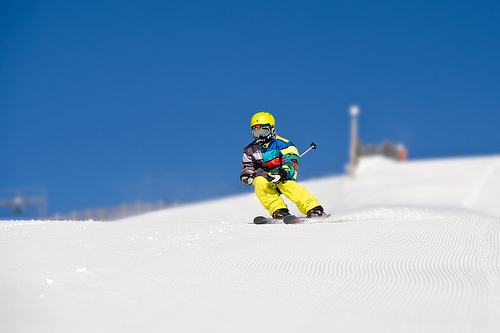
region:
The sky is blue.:
[30, 34, 150, 123]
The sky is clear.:
[34, 29, 195, 145]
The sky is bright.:
[35, 28, 204, 165]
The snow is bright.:
[108, 249, 313, 331]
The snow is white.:
[148, 244, 398, 325]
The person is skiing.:
[229, 104, 351, 231]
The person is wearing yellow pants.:
[213, 97, 340, 227]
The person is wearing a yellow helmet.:
[236, 95, 289, 142]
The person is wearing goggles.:
[237, 106, 283, 147]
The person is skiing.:
[223, 100, 343, 233]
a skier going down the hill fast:
[235, 102, 340, 232]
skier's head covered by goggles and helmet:
[244, 105, 281, 147]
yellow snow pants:
[245, 167, 339, 226]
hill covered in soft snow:
[6, 144, 498, 324]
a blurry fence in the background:
[26, 190, 202, 228]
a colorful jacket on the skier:
[233, 135, 303, 190]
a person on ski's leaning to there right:
[240, 103, 352, 236]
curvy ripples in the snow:
[226, 237, 492, 292]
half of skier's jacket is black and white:
[234, 138, 273, 192]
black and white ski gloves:
[234, 167, 306, 192]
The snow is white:
[231, 244, 302, 288]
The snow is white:
[250, 280, 337, 331]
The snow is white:
[272, 271, 319, 329]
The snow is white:
[290, 274, 325, 306]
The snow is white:
[290, 247, 340, 302]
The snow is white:
[268, 250, 336, 324]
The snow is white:
[287, 220, 359, 314]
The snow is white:
[310, 268, 382, 329]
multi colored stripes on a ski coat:
[257, 142, 293, 172]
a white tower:
[347, 99, 368, 168]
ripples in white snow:
[199, 212, 495, 312]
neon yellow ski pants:
[246, 178, 329, 235]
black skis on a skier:
[254, 212, 329, 227]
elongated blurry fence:
[43, 202, 178, 217]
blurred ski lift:
[4, 184, 59, 235]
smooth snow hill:
[23, 218, 248, 325]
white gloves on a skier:
[239, 166, 280, 185]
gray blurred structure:
[354, 137, 413, 165]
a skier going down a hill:
[218, 88, 408, 280]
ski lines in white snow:
[325, 224, 462, 331]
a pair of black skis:
[249, 210, 331, 227]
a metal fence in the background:
[48, 201, 169, 222]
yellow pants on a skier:
[246, 173, 322, 214]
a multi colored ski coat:
[240, 140, 302, 179]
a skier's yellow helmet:
[246, 112, 277, 140]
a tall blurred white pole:
[346, 104, 359, 170]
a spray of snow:
[329, 202, 413, 231]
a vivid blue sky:
[54, 27, 202, 152]